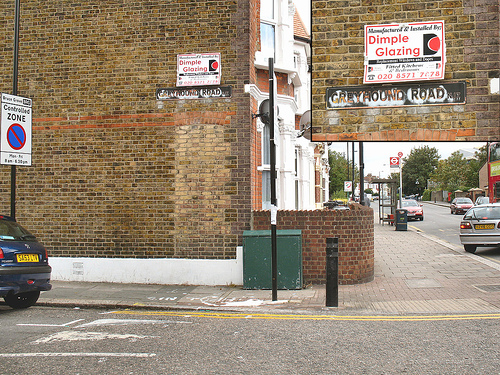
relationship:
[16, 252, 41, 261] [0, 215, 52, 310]
license plate on car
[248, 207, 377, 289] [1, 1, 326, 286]
brick wall on building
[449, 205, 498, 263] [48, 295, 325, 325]
car on curb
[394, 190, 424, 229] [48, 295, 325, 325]
car on curb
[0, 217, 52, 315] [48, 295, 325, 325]
car on curb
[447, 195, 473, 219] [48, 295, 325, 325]
car on curb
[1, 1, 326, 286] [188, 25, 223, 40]
building made of brick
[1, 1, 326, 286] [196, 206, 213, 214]
building made of brick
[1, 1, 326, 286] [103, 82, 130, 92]
building made of brick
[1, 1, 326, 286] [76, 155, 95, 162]
building made of brick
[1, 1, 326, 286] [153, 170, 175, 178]
building made of brick